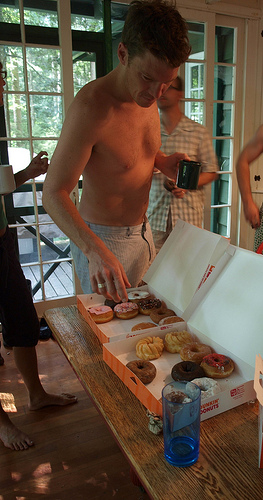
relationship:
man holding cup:
[41, 0, 192, 306] [175, 158, 200, 190]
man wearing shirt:
[151, 74, 218, 238] [147, 114, 216, 229]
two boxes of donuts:
[75, 246, 220, 342] [95, 287, 231, 399]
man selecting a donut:
[41, 0, 192, 306] [113, 301, 139, 320]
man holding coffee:
[41, 0, 192, 306] [177, 156, 198, 192]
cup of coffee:
[175, 155, 202, 193] [177, 156, 198, 192]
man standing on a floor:
[0, 53, 79, 453] [0, 323, 151, 497]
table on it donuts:
[43, 294, 263, 497] [86, 303, 113, 321]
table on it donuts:
[43, 294, 263, 497] [125, 359, 156, 383]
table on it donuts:
[43, 294, 263, 497] [169, 360, 206, 382]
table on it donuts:
[43, 294, 263, 497] [200, 354, 234, 379]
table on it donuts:
[43, 294, 263, 497] [134, 335, 163, 360]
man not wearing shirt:
[41, 0, 192, 306] [154, 113, 217, 236]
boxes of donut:
[76, 219, 261, 430] [86, 304, 113, 323]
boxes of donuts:
[76, 219, 261, 430] [125, 359, 156, 383]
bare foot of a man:
[25, 390, 79, 412] [0, 53, 79, 453]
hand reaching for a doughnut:
[86, 244, 134, 304] [92, 296, 212, 352]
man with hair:
[41, 0, 192, 306] [119, 1, 192, 69]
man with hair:
[151, 74, 218, 238] [175, 74, 182, 89]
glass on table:
[160, 379, 199, 467] [34, 295, 253, 482]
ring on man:
[96, 281, 106, 289] [41, 0, 192, 306]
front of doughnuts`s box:
[102, 344, 173, 431] [102, 243, 262, 430]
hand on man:
[88, 245, 131, 304] [41, 0, 192, 306]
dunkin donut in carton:
[167, 356, 208, 382] [101, 243, 262, 430]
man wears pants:
[103, 21, 181, 119] [66, 221, 157, 292]